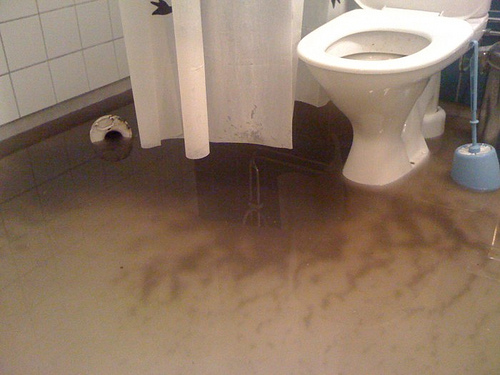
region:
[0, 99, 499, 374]
a flooded bathroom floor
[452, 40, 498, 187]
a blue toilet scrub brush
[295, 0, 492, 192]
a white toilet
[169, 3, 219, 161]
a white polein a bathroom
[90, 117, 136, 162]
a roll of toilet paper in the water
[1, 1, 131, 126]
a white tile bathroom wall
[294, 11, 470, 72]
a white seat on a toilet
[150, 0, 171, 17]
a dark spot where paint chipped off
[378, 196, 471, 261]
dirt collecting under the water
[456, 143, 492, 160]
the white head of a scrub brush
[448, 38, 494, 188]
a scrub brush in it's holder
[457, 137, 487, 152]
the white scrubber end of a toilet brush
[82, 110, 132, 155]
a roll of toilet paper in the water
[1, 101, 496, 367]
a flooded bathroom floor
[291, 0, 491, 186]
a white toilet in a bathroom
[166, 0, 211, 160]
a white post in a bathroom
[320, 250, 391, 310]
a dirt ripple on the ground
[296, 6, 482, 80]
a white toilet seat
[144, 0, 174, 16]
a dark spot where paint chipped off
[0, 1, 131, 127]
a white tile wall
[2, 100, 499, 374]
There is water in the floor of the bathroom.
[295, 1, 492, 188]
There is a toilet on the bathroom floor.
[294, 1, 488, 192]
The toilet is white in color.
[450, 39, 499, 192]
There is a toilet brush next to the toilet.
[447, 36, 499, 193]
The toilet brush is blue in color.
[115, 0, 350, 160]
There is a shower curtain hanging in bathroom.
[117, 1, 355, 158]
Shower curtain is white with a partial design.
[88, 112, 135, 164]
Shower drain located on floor of shower area.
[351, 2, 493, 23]
Toilet lid is located in the up position.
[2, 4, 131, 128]
Tile on wall is white in color.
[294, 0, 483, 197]
white porcelain toilet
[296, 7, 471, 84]
toilet seat is down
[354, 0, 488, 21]
toilet lid is up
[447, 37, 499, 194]
toilet brush in its holder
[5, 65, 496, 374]
brown murky water on the floor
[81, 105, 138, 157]
a roll of toilet paper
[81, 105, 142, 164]
toilet paper in the water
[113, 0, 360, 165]
white curtain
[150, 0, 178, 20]
black bird on the curtain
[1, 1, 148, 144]
white tiles on the wall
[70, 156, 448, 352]
A flooded bathroom floor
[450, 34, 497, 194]
A toilet cleaning utensil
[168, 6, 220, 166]
A white pole in the bathroom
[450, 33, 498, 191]
A blue toilet cleaning utensil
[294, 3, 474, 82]
A white toilet seat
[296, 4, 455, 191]
A toilet in the bathroom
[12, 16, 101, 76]
White tiles in the bathroom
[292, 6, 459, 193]
A white toilet with the lid up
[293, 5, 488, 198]
toilet on the side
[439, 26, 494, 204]
a toilet bowl cleaner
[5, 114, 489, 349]
water in the floor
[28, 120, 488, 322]
brown dirt on the floor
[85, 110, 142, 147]
valve on the floor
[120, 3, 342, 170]
bottom of a curtain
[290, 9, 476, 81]
seat of the toilet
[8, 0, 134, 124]
a white tile wall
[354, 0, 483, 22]
bottom of seat cover